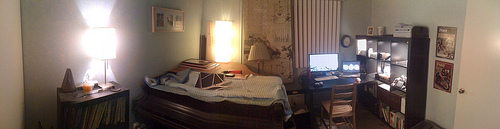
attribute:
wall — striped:
[291, 0, 340, 71]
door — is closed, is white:
[451, 0, 498, 127]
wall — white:
[20, 17, 70, 79]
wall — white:
[443, 82, 470, 124]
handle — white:
[457, 74, 478, 102]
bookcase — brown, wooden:
[51, 78, 133, 125]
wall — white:
[409, 7, 494, 125]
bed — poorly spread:
[132, 67, 289, 125]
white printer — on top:
[393, 20, 428, 39]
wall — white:
[406, 15, 490, 126]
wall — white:
[467, 6, 499, 61]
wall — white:
[21, 6, 67, 94]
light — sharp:
[74, 15, 126, 71]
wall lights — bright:
[80, 0, 117, 85]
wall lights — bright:
[215, 20, 232, 61]